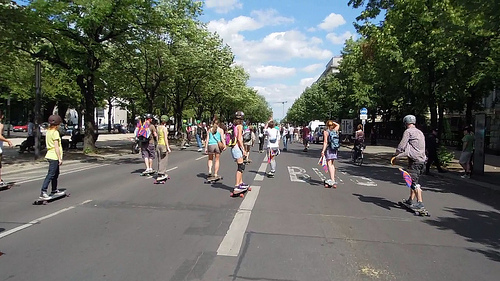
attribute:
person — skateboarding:
[231, 113, 253, 202]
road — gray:
[103, 99, 437, 228]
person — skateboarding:
[210, 111, 225, 182]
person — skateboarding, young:
[51, 118, 65, 200]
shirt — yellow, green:
[46, 132, 67, 161]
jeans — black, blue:
[40, 158, 63, 195]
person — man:
[389, 115, 435, 220]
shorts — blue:
[230, 146, 244, 157]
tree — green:
[367, 8, 467, 184]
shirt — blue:
[206, 130, 220, 142]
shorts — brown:
[205, 147, 220, 152]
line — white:
[225, 119, 273, 227]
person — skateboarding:
[320, 123, 348, 186]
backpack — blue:
[327, 126, 341, 148]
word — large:
[289, 161, 379, 194]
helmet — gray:
[400, 111, 417, 123]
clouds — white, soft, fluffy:
[213, 18, 296, 71]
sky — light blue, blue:
[162, 3, 360, 127]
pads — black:
[241, 163, 246, 170]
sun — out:
[341, 4, 392, 50]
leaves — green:
[426, 22, 474, 59]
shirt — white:
[265, 129, 283, 155]